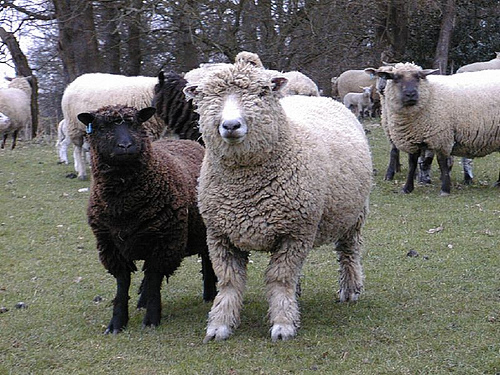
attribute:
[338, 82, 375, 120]
sheep — baby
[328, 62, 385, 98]
sheep — white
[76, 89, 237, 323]
sheep — looking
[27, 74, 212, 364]
sheep — small, black-wooled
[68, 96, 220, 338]
sheep — brown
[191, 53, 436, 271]
large sheep — white-wooled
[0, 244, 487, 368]
field — green, grassy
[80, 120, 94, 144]
blue tag — small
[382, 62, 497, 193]
sheep — standing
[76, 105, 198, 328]
sheep — standing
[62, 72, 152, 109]
sheep — standing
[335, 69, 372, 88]
sheep — standing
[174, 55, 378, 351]
white sheep — whitee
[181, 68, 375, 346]
sheep — standing, white, looking, thick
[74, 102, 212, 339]
sheep — black, dark brown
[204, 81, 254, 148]
face — white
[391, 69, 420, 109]
face — black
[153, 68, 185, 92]
face — black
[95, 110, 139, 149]
face — black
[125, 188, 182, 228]
wool — brown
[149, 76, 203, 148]
sheep — brown